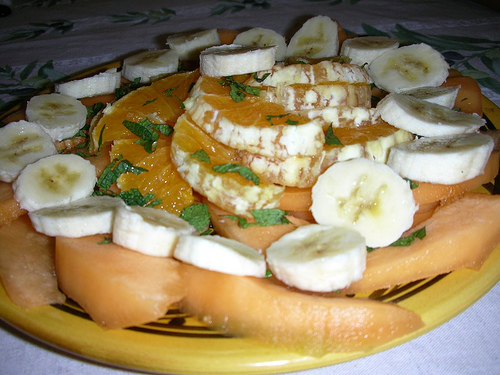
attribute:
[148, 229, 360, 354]
melon — orange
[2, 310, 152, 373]
shadow — underneath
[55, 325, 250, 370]
plate — yellow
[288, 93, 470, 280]
bananas — sliced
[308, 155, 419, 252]
banana — sliced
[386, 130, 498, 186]
banana — sliced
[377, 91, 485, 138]
banana — sliced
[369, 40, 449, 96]
banana — sliced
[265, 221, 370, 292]
banana — sliced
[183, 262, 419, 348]
melon — orange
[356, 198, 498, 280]
melon — orange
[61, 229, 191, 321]
melon — orange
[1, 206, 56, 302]
melon — orange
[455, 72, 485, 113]
melon — orange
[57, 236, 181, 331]
fruit — arrenged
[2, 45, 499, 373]
plate — yellow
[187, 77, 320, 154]
fruit — arrenged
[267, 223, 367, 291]
fruit — organized, arrenged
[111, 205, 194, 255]
fruit — arrenged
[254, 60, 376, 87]
fruit — arrenged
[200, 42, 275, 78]
banana — slice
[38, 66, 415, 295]
bananas — sliced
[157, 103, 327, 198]
oranges — sliced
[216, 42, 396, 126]
oranges — sliced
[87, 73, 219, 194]
oranges — sliced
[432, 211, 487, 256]
cantaloupe — sliced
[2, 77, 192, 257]
bananas — sliced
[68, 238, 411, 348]
melon — orange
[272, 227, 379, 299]
banana — sliced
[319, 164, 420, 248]
banana — sliced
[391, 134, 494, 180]
banana — sliced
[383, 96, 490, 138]
banana — sliced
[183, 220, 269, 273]
banana — sliced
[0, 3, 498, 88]
table cloth — floral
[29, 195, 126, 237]
banana slice — sliced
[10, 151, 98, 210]
banana slice — sliced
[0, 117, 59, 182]
banana slice — sliced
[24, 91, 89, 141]
banana slice — sliced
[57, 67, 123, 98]
banana slice — sliced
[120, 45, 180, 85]
banana slice — sliced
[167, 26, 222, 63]
banana slice — sliced